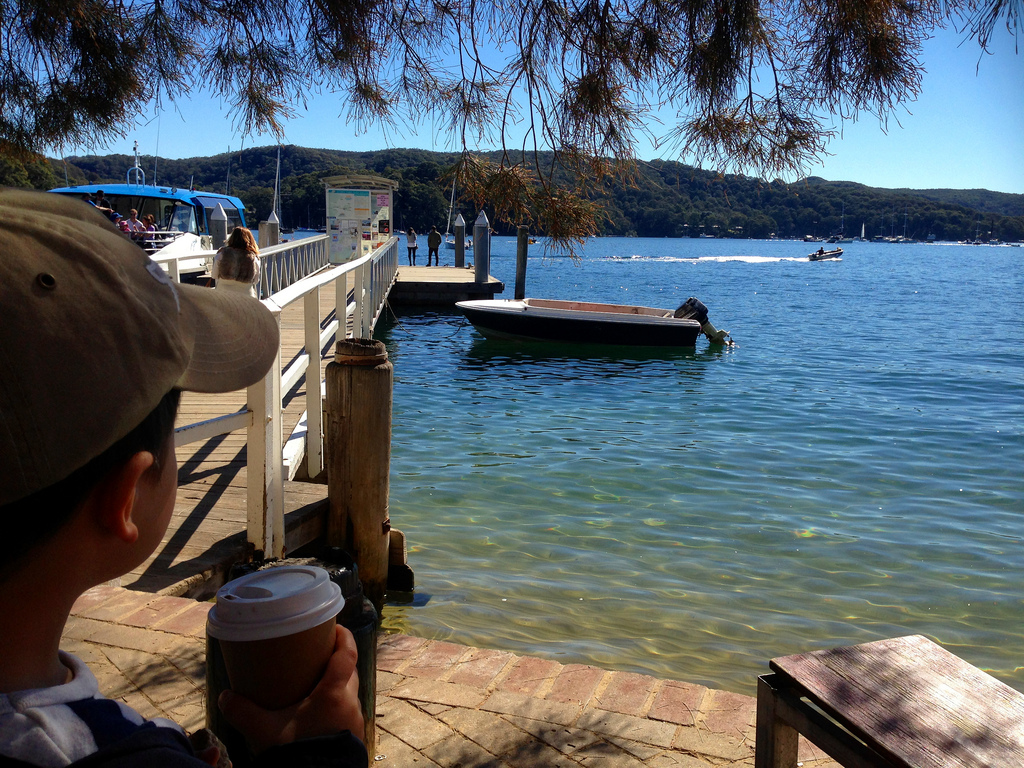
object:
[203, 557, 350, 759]
cup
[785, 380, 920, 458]
ripples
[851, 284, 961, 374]
ripples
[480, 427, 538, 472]
ripples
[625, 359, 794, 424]
ripples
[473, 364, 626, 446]
ripples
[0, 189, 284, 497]
hat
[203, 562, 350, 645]
lid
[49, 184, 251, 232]
tarp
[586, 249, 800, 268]
wake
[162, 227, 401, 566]
fence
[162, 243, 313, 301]
fence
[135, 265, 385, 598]
dock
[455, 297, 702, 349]
boat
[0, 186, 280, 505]
baseball hat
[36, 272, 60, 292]
hole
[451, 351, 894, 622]
ripples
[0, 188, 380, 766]
man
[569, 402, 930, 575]
lake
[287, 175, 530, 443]
dock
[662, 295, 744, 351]
motor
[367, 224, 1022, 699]
lake